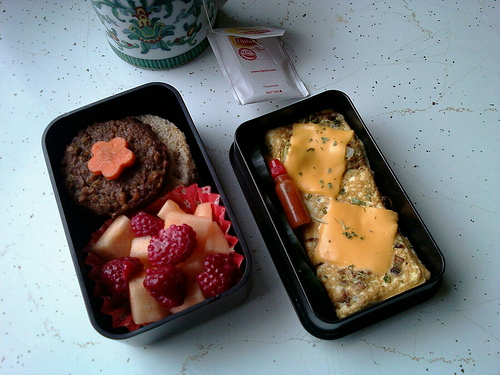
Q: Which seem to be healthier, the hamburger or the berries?
A: The berries are healthier than the hamburger.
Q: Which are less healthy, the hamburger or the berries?
A: The hamburger are less healthy than the berries.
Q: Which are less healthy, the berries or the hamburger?
A: The hamburger are less healthy than the berries.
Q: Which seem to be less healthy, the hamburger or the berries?
A: The hamburger are less healthy than the berries.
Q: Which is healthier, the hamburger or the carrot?
A: The carrot is healthier than the hamburger.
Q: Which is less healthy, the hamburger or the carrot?
A: The hamburger is less healthy than the carrot.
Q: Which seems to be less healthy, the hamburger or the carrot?
A: The hamburger is less healthy than the carrot.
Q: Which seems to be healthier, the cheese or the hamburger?
A: The cheese is healthier than the hamburger.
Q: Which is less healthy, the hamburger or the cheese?
A: The hamburger is less healthy than the cheese.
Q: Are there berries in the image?
A: Yes, there are berries.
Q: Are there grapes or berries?
A: Yes, there are berries.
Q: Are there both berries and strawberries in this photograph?
A: No, there are berries but no strawberries.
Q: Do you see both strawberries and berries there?
A: No, there are berries but no strawberries.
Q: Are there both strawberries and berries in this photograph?
A: No, there are berries but no strawberries.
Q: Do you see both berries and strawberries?
A: No, there are berries but no strawberries.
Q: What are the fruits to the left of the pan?
A: The fruits are berries.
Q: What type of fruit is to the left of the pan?
A: The fruits are berries.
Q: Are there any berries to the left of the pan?
A: Yes, there are berries to the left of the pan.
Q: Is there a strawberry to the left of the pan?
A: No, there are berries to the left of the pan.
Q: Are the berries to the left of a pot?
A: No, the berries are to the left of the pan.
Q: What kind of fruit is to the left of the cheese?
A: The fruits are berries.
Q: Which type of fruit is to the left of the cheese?
A: The fruits are berries.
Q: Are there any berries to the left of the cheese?
A: Yes, there are berries to the left of the cheese.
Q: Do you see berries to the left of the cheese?
A: Yes, there are berries to the left of the cheese.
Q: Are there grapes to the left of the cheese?
A: No, there are berries to the left of the cheese.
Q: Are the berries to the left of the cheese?
A: Yes, the berries are to the left of the cheese.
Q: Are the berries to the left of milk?
A: No, the berries are to the left of the cheese.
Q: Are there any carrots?
A: Yes, there is a carrot.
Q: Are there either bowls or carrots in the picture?
A: Yes, there is a carrot.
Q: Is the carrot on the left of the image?
A: Yes, the carrot is on the left of the image.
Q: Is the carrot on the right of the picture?
A: No, the carrot is on the left of the image.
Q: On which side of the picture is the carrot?
A: The carrot is on the left of the image.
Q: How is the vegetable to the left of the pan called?
A: The vegetable is a carrot.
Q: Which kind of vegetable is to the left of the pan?
A: The vegetable is a carrot.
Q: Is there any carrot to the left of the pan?
A: Yes, there is a carrot to the left of the pan.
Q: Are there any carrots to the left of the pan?
A: Yes, there is a carrot to the left of the pan.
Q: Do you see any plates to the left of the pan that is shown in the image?
A: No, there is a carrot to the left of the pan.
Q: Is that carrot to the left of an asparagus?
A: No, the carrot is to the left of the pan.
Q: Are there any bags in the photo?
A: Yes, there is a bag.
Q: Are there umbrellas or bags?
A: Yes, there is a bag.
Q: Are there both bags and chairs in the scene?
A: No, there is a bag but no chairs.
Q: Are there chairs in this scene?
A: No, there are no chairs.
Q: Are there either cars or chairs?
A: No, there are no chairs or cars.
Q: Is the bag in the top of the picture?
A: Yes, the bag is in the top of the image.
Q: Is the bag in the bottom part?
A: No, the bag is in the top of the image.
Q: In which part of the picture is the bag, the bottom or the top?
A: The bag is in the top of the image.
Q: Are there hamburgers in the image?
A: Yes, there is a hamburger.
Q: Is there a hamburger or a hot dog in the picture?
A: Yes, there is a hamburger.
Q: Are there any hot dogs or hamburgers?
A: Yes, there is a hamburger.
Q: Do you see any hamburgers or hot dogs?
A: Yes, there is a hamburger.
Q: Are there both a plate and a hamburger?
A: No, there is a hamburger but no plates.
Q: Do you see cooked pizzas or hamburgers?
A: Yes, there is a cooked hamburger.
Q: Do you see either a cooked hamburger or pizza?
A: Yes, there is a cooked hamburger.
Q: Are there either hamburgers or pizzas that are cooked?
A: Yes, the hamburger is cooked.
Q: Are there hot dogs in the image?
A: No, there are no hot dogs.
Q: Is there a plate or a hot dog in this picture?
A: No, there are no hot dogs or plates.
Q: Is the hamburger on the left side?
A: Yes, the hamburger is on the left of the image.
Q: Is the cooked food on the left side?
A: Yes, the hamburger is on the left of the image.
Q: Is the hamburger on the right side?
A: No, the hamburger is on the left of the image.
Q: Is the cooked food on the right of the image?
A: No, the hamburger is on the left of the image.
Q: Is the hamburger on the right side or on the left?
A: The hamburger is on the left of the image.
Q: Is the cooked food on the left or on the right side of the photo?
A: The hamburger is on the left of the image.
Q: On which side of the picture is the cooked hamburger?
A: The hamburger is on the left of the image.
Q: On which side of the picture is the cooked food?
A: The hamburger is on the left of the image.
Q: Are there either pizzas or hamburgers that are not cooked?
A: No, there is a hamburger but it is cooked.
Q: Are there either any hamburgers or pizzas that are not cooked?
A: No, there is a hamburger but it is cooked.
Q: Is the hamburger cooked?
A: Yes, the hamburger is cooked.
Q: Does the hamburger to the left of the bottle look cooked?
A: Yes, the hamburger is cooked.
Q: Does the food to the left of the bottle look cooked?
A: Yes, the hamburger is cooked.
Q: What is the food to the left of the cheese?
A: The food is a hamburger.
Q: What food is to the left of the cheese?
A: The food is a hamburger.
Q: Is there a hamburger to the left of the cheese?
A: Yes, there is a hamburger to the left of the cheese.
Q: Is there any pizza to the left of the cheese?
A: No, there is a hamburger to the left of the cheese.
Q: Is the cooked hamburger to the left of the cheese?
A: Yes, the hamburger is to the left of the cheese.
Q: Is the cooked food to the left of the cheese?
A: Yes, the hamburger is to the left of the cheese.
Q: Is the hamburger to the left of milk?
A: No, the hamburger is to the left of the cheese.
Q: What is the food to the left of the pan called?
A: The food is a hamburger.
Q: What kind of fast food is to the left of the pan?
A: The food is a hamburger.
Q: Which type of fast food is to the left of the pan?
A: The food is a hamburger.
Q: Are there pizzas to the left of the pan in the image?
A: No, there is a hamburger to the left of the pan.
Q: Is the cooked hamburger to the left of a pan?
A: Yes, the hamburger is to the left of a pan.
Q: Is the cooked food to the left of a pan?
A: Yes, the hamburger is to the left of a pan.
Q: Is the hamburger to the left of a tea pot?
A: No, the hamburger is to the left of a pan.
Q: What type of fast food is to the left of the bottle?
A: The food is a hamburger.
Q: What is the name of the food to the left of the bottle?
A: The food is a hamburger.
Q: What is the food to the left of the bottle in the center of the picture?
A: The food is a hamburger.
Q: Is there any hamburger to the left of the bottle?
A: Yes, there is a hamburger to the left of the bottle.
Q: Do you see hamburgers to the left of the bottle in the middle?
A: Yes, there is a hamburger to the left of the bottle.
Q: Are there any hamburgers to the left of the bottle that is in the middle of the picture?
A: Yes, there is a hamburger to the left of the bottle.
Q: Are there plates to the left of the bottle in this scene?
A: No, there is a hamburger to the left of the bottle.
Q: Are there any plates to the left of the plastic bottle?
A: No, there is a hamburger to the left of the bottle.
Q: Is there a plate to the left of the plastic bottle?
A: No, there is a hamburger to the left of the bottle.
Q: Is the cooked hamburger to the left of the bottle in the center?
A: Yes, the hamburger is to the left of the bottle.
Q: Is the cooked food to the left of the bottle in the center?
A: Yes, the hamburger is to the left of the bottle.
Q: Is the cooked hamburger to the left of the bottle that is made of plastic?
A: Yes, the hamburger is to the left of the bottle.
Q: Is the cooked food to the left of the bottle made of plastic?
A: Yes, the hamburger is to the left of the bottle.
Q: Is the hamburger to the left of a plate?
A: No, the hamburger is to the left of the bottle.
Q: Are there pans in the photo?
A: Yes, there is a pan.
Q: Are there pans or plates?
A: Yes, there is a pan.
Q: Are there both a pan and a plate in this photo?
A: No, there is a pan but no plates.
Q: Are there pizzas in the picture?
A: No, there are no pizzas.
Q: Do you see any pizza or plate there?
A: No, there are no pizzas or plates.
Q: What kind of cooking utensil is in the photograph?
A: The cooking utensil is a pan.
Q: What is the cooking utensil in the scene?
A: The cooking utensil is a pan.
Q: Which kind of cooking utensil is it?
A: The cooking utensil is a pan.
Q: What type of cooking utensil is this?
A: This is a pan.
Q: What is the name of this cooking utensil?
A: This is a pan.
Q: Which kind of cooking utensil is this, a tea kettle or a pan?
A: This is a pan.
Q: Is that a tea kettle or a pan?
A: That is a pan.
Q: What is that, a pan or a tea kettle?
A: That is a pan.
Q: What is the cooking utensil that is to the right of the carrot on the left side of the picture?
A: The cooking utensil is a pan.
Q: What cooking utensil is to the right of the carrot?
A: The cooking utensil is a pan.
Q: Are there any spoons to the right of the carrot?
A: No, there is a pan to the right of the carrot.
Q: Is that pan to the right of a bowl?
A: No, the pan is to the right of the carrot.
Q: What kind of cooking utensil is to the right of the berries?
A: The cooking utensil is a pan.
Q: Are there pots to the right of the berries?
A: No, there is a pan to the right of the berries.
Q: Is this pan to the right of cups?
A: No, the pan is to the right of the berries.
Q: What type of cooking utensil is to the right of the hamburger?
A: The cooking utensil is a pan.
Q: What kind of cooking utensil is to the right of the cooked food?
A: The cooking utensil is a pan.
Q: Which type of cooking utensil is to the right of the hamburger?
A: The cooking utensil is a pan.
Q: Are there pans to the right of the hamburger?
A: Yes, there is a pan to the right of the hamburger.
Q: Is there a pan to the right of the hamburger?
A: Yes, there is a pan to the right of the hamburger.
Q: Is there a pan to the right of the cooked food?
A: Yes, there is a pan to the right of the hamburger.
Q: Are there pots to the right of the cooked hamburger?
A: No, there is a pan to the right of the hamburger.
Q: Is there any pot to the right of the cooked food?
A: No, there is a pan to the right of the hamburger.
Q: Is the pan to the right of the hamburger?
A: Yes, the pan is to the right of the hamburger.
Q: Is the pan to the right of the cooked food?
A: Yes, the pan is to the right of the hamburger.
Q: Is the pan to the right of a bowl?
A: No, the pan is to the right of the hamburger.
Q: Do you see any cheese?
A: Yes, there is cheese.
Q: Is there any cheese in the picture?
A: Yes, there is cheese.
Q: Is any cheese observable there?
A: Yes, there is cheese.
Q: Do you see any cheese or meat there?
A: Yes, there is cheese.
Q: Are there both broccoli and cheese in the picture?
A: No, there is cheese but no broccoli.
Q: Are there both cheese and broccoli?
A: No, there is cheese but no broccoli.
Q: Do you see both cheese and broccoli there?
A: No, there is cheese but no broccoli.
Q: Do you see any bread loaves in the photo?
A: No, there are no bread loaves.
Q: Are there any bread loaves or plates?
A: No, there are no bread loaves or plates.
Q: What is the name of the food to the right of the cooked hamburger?
A: The food is cheese.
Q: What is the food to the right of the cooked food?
A: The food is cheese.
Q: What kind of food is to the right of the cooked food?
A: The food is cheese.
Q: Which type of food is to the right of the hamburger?
A: The food is cheese.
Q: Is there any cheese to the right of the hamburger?
A: Yes, there is cheese to the right of the hamburger.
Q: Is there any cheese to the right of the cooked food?
A: Yes, there is cheese to the right of the hamburger.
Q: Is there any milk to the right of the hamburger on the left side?
A: No, there is cheese to the right of the hamburger.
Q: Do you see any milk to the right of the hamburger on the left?
A: No, there is cheese to the right of the hamburger.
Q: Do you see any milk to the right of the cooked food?
A: No, there is cheese to the right of the hamburger.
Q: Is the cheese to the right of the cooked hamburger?
A: Yes, the cheese is to the right of the hamburger.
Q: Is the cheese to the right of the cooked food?
A: Yes, the cheese is to the right of the hamburger.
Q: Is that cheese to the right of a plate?
A: No, the cheese is to the right of the hamburger.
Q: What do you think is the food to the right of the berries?
A: The food is cheese.